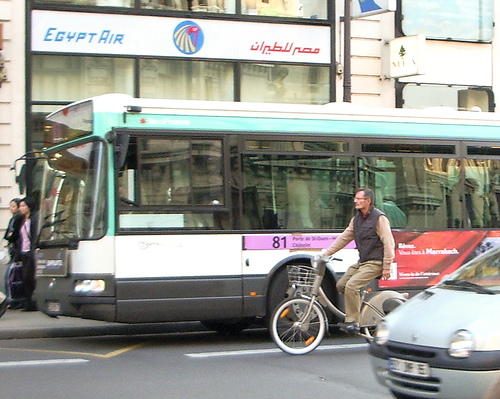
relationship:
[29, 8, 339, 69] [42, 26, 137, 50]
sign reads egypt air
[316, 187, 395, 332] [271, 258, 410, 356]
man on bike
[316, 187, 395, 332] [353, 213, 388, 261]
man has jacket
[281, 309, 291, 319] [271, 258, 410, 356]
reflector on bike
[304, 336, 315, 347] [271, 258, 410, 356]
reflector on bike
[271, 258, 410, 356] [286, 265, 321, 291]
bike with basket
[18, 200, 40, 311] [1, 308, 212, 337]
woman on sidewalk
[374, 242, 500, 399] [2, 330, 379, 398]
car in street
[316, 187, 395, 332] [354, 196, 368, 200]
man has glasses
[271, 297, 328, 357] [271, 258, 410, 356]
tire on bike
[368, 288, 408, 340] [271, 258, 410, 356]
tire on bike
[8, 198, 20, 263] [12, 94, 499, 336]
woman near bus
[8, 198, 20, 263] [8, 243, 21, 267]
woman pants are black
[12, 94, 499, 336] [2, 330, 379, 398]
bus on street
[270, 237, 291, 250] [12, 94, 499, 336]
number on bus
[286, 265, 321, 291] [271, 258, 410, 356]
basket on bike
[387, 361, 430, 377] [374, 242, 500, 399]
license plant on car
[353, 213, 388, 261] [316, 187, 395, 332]
jacket on man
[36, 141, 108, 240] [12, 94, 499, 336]
windshield on bus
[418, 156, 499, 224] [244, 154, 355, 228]
reflection on window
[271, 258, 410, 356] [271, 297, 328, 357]
bike with white wheel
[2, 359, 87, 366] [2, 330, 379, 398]
line on street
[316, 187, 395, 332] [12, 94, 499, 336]
man near bus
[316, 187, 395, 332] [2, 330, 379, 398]
man on street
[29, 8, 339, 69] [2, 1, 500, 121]
sign on building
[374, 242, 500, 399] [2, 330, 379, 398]
car on street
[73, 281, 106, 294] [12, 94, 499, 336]
headlight on bus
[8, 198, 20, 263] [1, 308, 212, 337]
woman on sidewalk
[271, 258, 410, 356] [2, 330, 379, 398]
bike on street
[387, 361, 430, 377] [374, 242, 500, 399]
license plate on car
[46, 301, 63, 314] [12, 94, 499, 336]
license plate on bus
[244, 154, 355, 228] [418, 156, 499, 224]
window with reflection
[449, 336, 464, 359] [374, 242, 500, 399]
headlight on car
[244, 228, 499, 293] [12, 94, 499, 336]
ad on bus